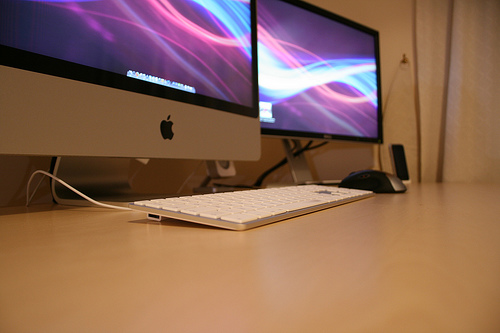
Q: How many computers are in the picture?
A: Two.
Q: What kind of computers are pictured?
A: Macs.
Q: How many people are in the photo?
A: Zero.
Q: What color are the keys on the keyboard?
A: White.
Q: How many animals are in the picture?
A: Zero.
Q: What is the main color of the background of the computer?
A: Purple.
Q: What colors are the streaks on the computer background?
A: Blue and pink.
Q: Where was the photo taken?
A: In an office.